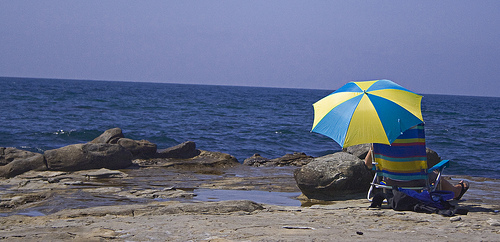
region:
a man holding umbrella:
[356, 126, 442, 225]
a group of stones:
[27, 113, 367, 198]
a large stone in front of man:
[291, 140, 385, 229]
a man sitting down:
[356, 143, 445, 221]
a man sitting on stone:
[346, 135, 454, 225]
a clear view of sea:
[29, 68, 496, 181]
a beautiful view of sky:
[17, 7, 496, 94]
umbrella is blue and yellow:
[310, 74, 424, 147]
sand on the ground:
[125, 215, 227, 230]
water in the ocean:
[114, 93, 241, 143]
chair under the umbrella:
[363, 130, 436, 187]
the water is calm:
[110, 86, 262, 145]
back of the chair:
[370, 158, 425, 194]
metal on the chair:
[363, 174, 378, 200]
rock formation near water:
[38, 140, 202, 190]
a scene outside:
[3, 3, 484, 240]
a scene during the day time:
[0, 5, 498, 220]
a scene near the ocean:
[3, 3, 497, 238]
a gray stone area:
[0, 109, 497, 240]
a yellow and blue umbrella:
[300, 65, 434, 157]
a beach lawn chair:
[349, 75, 481, 217]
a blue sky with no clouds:
[0, 0, 498, 117]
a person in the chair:
[357, 112, 477, 223]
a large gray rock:
[282, 138, 394, 208]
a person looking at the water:
[15, 8, 492, 235]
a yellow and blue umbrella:
[308, 78, 425, 150]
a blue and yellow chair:
[369, 128, 445, 208]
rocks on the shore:
[3, 123, 303, 175]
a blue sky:
[1, 75, 494, 179]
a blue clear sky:
[1, 0, 498, 96]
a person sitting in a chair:
[365, 126, 469, 213]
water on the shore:
[178, 183, 309, 219]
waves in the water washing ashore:
[4, 77, 499, 177]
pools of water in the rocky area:
[9, 163, 296, 221]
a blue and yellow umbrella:
[307, 78, 428, 148]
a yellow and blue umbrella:
[305, 71, 430, 153]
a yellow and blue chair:
[367, 124, 431, 208]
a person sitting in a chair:
[312, 73, 472, 215]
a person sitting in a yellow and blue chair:
[308, 70, 469, 216]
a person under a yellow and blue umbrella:
[310, 70, 466, 215]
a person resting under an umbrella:
[307, 71, 472, 216]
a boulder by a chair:
[295, 141, 379, 202]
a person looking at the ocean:
[312, 70, 474, 215]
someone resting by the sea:
[310, 63, 471, 221]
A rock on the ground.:
[189, 147, 219, 169]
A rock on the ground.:
[239, 155, 266, 167]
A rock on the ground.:
[266, 149, 305, 169]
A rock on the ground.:
[152, 136, 184, 156]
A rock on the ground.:
[185, 150, 226, 162]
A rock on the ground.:
[113, 137, 143, 152]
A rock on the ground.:
[85, 125, 118, 139]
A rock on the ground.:
[48, 142, 153, 167]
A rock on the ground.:
[75, 165, 124, 174]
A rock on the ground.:
[153, 182, 187, 195]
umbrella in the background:
[284, 42, 494, 214]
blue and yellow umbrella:
[281, 50, 475, 191]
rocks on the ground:
[26, 120, 296, 217]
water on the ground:
[169, 170, 311, 200]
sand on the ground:
[124, 185, 426, 240]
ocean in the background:
[61, 66, 353, 135]